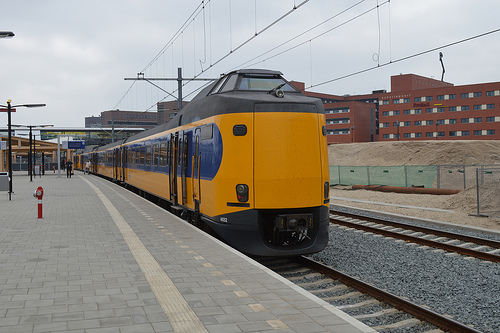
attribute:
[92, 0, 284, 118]
wires — electric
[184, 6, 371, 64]
wires — black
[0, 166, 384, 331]
platform — grey, white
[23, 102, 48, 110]
light — off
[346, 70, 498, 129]
building — large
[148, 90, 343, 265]
train — yellow, blue, grey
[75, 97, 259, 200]
yellow train — blue, grey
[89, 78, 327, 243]
train — yellow, blue, grey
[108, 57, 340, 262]
train — blue, yellow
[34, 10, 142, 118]
sky — gray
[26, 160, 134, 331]
road — tile, cement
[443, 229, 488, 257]
railway — metallic, rusty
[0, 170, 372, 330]
tile road — cement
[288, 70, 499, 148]
building — red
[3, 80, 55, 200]
poles — light, lined up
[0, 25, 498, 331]
train station — brown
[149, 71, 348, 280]
train — yellow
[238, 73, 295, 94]
windshield — high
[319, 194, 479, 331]
railway — metalic, rusty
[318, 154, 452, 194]
fence — green